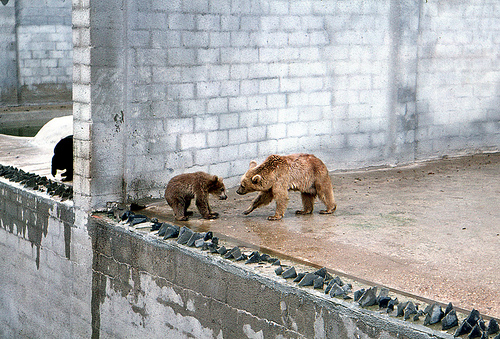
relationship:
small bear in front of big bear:
[160, 168, 230, 223] [231, 147, 341, 220]